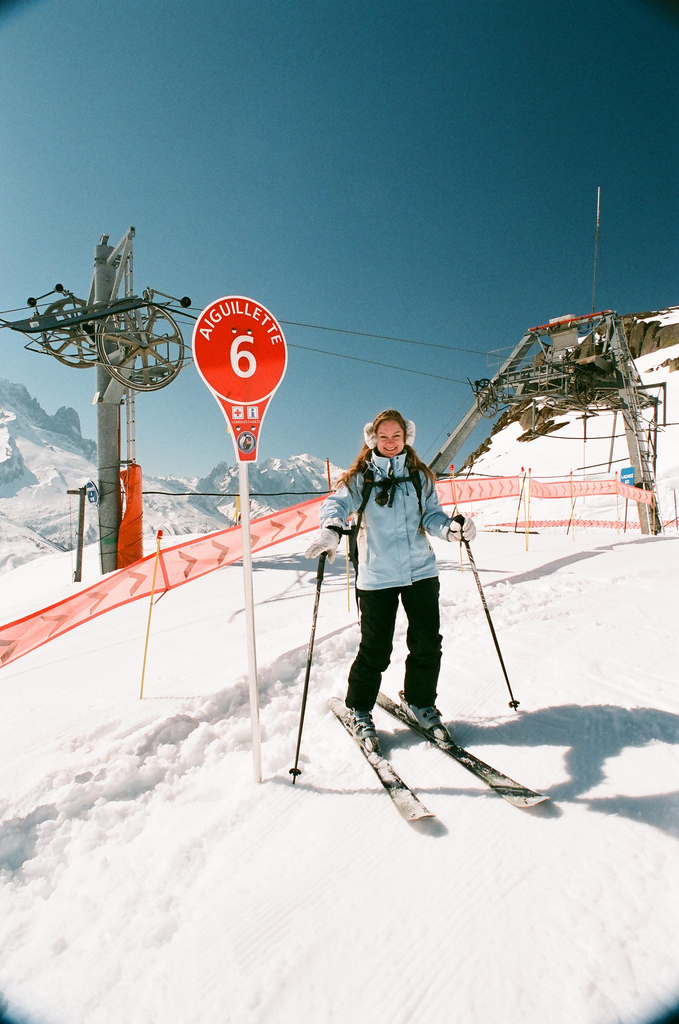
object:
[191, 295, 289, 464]
sign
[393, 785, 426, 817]
snow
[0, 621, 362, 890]
track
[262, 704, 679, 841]
shadow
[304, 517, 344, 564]
glove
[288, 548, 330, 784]
pole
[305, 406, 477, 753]
girl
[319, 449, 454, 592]
coat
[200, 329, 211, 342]
letter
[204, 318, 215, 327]
letter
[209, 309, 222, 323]
letter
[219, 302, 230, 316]
letter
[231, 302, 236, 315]
letter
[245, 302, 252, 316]
letter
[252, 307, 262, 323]
letter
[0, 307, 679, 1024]
snow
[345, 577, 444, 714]
pants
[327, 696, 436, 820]
ski